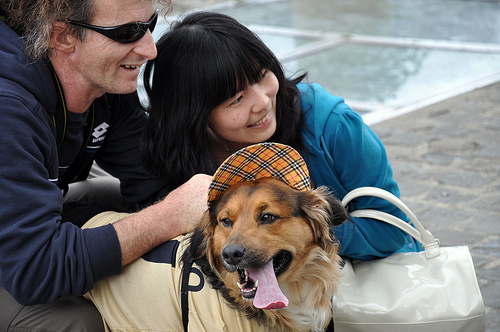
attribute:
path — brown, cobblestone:
[378, 49, 494, 269]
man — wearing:
[4, 0, 193, 262]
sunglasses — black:
[82, 12, 164, 47]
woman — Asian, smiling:
[136, 14, 427, 256]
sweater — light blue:
[276, 79, 411, 248]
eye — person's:
[226, 90, 248, 112]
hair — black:
[139, 7, 315, 194]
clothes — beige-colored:
[70, 199, 292, 330]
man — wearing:
[3, 5, 155, 330]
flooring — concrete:
[435, 126, 475, 187]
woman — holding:
[163, 6, 310, 153]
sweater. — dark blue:
[0, 100, 140, 286]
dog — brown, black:
[192, 177, 349, 329]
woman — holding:
[147, 12, 414, 271]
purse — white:
[248, 157, 483, 329]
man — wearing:
[4, 3, 242, 328]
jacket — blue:
[1, 56, 168, 298]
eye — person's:
[257, 61, 275, 84]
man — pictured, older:
[0, 3, 212, 330]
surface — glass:
[333, 15, 495, 118]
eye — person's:
[258, 71, 268, 81]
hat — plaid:
[187, 139, 334, 201]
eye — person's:
[222, 86, 249, 110]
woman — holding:
[148, 22, 338, 174]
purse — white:
[331, 192, 481, 329]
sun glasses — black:
[60, 6, 160, 42]